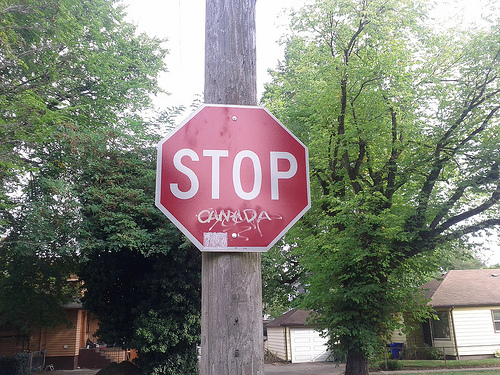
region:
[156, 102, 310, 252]
red sign has eight sides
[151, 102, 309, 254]
stop sign in front of tan house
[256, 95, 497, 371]
treen in front of tan house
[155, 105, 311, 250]
stop sign hanging on pole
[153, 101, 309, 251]
stop sign hanging on wooden post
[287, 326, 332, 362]
garage door is white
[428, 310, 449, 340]
window on tan house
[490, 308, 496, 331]
window on tan house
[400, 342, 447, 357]
bush in front of tan house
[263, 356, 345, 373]
paved driveway in front of garage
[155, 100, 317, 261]
a stop sign on a pole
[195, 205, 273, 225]
Canada written on a stop sign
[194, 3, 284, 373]
a pole with a sign on it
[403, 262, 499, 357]
a house in the distance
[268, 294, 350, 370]
a garage behind a tree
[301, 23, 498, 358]
a tree in front of a house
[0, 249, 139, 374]
an orange house with steps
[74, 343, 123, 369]
steps leading to a house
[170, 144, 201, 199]
a white letter S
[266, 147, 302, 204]
a white letter P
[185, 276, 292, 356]
tall gray wooden pole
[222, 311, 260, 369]
tiny lines in the pole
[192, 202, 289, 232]
white graffiti words on the sign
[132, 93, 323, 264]
red sign on the post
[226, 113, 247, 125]
tiny silver bolt in red sign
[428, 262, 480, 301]
red roof on house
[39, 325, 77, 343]
yellow shingles on wall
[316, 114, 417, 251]
bright leafy green tree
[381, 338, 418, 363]
tall blue trash can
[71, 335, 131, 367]
small wall on side of house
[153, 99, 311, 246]
sign is shaped like an octagon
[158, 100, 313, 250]
red sign with white writing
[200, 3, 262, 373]
red sign on wooden post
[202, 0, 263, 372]
wooden post holding stop sign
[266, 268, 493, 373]
roof on house is black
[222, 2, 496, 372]
treen has bushy green branches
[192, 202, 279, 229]
"Cananda" written on stop sign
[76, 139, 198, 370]
tree is next to tree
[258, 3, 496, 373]
tree is next to tree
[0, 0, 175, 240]
tree is next to tree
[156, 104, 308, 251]
red and white stop sign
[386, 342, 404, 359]
blue trash can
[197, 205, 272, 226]
writing on the stop sign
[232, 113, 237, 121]
metal bolt holding stop sign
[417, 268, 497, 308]
house's roof is brown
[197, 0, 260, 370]
large wooden pole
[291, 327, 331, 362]
white garage door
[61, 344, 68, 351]
white vent on the house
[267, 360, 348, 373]
concrete drive way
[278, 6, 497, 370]
tall green tree